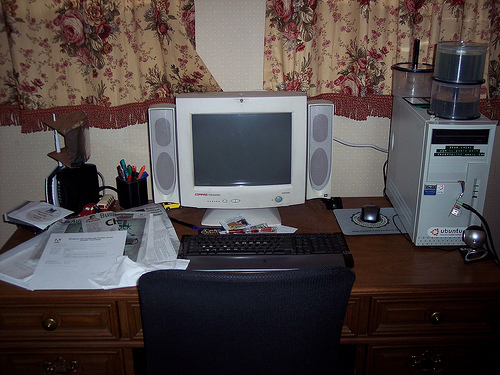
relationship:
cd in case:
[419, 33, 491, 113] [429, 69, 483, 119]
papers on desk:
[2, 207, 187, 307] [3, 183, 498, 360]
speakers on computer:
[136, 107, 231, 218] [156, 103, 308, 188]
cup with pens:
[111, 170, 149, 206] [112, 159, 164, 210]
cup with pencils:
[111, 170, 149, 206] [112, 159, 146, 195]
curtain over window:
[6, 18, 169, 110] [2, 1, 223, 135]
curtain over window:
[265, 15, 382, 82] [2, 1, 223, 135]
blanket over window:
[1, 3, 224, 129] [2, 1, 223, 135]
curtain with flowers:
[260, 0, 496, 105] [3, 3, 491, 115]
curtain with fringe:
[260, 0, 496, 105] [2, 92, 498, 130]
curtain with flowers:
[2, 0, 226, 136] [3, 3, 491, 115]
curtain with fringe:
[2, 0, 226, 136] [2, 92, 498, 130]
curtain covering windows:
[260, 0, 496, 105] [4, 2, 496, 131]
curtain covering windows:
[2, 0, 226, 136] [4, 2, 496, 131]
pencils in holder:
[117, 155, 148, 178] [116, 170, 148, 207]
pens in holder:
[114, 157, 149, 177] [116, 170, 148, 207]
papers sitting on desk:
[24, 221, 139, 299] [1, 196, 499, 372]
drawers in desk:
[0, 296, 498, 372] [4, 247, 498, 357]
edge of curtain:
[109, 117, 127, 130] [2, 0, 226, 136]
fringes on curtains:
[0, 80, 202, 134] [2, 2, 499, 142]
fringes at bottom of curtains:
[0, 80, 202, 134] [2, 2, 499, 142]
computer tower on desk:
[383, 97, 497, 252] [356, 237, 421, 278]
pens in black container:
[107, 156, 147, 181] [114, 172, 149, 209]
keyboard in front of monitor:
[175, 229, 353, 269] [115, 66, 368, 236]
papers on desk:
[3, 199, 302, 288] [1, 196, 499, 372]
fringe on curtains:
[1, 97, 193, 132] [0, 0, 227, 128]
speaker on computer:
[304, 98, 334, 201] [174, 88, 307, 226]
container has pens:
[110, 168, 158, 219] [110, 157, 151, 188]